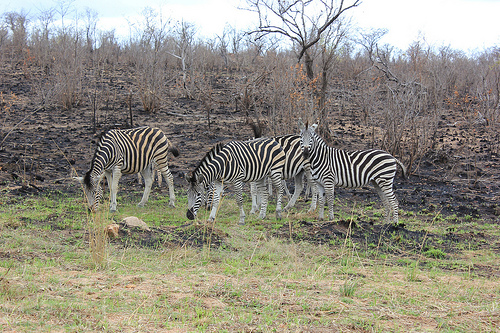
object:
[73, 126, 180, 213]
zebra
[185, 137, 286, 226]
zebra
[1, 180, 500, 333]
field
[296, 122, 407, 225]
zebra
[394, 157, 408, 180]
tail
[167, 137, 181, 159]
tail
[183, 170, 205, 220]
head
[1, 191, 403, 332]
grass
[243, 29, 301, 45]
branch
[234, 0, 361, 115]
tree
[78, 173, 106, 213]
head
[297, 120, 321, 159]
head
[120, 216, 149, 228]
rock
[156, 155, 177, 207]
leg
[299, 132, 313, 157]
face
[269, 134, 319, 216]
zebra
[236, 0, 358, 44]
top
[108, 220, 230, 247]
dirt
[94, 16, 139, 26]
cloud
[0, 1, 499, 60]
sky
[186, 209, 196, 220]
nose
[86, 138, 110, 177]
neck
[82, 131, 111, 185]
mane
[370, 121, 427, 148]
brush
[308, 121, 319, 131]
ear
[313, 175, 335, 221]
leg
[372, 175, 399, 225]
leg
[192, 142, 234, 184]
mane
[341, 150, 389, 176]
stripe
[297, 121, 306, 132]
ear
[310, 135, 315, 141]
eye